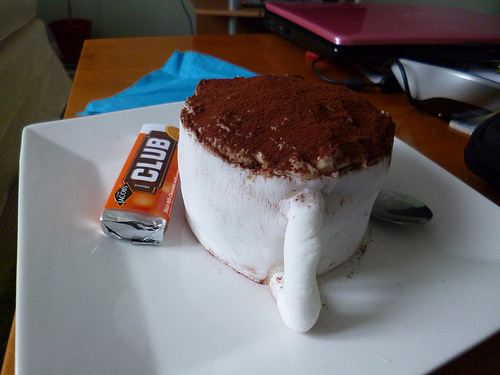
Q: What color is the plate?
A: White.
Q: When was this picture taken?
A: Daytime.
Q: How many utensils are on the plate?
A: 1.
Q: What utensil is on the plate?
A: Spoon.